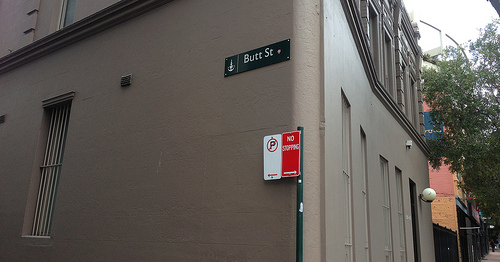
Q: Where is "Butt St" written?
A: On a sign.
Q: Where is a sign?
A: On side of a building.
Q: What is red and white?
A: Street sign.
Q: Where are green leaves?
A: On a tree.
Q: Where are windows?
A: On the building.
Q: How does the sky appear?
A: White.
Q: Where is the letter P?
A: On a white sign.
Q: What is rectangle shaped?
A: Windows.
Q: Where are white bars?
A: On the window.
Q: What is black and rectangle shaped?
A: A sign.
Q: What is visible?
A: The sign.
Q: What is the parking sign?
A: Red and white.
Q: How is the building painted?
A: Grey.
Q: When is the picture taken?
A: Daytime.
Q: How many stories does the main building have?
A: Two.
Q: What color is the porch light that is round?
A: White.